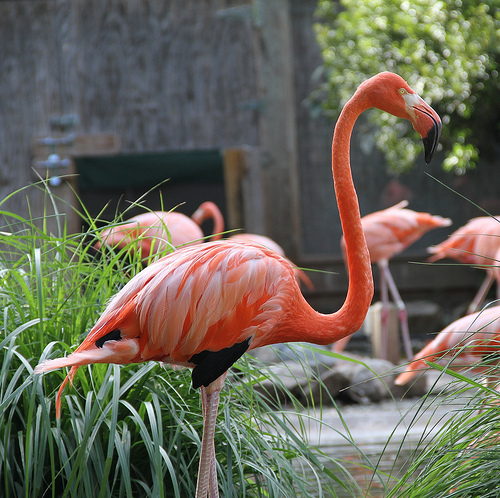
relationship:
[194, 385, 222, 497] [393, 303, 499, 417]
legs of bird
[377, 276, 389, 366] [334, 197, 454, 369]
leg of flamingo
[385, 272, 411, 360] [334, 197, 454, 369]
leg of flamingo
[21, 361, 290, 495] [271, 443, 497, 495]
grass at edge of water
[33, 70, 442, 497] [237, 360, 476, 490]
bird standing in water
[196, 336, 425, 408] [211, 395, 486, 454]
boulder near edge of water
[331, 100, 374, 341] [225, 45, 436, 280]
neck of bird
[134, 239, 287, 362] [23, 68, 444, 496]
feathers on side of bird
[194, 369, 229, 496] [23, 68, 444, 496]
legs of bird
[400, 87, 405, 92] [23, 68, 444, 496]
eye of bird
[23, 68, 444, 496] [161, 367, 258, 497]
bird has legs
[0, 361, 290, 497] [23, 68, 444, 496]
grass behind bird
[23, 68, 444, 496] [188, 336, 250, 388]
bird has black feathers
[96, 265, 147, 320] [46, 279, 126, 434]
feather on tail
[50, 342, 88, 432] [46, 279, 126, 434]
feather on tail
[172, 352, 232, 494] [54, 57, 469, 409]
legs on flamingo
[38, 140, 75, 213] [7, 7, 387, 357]
light on building